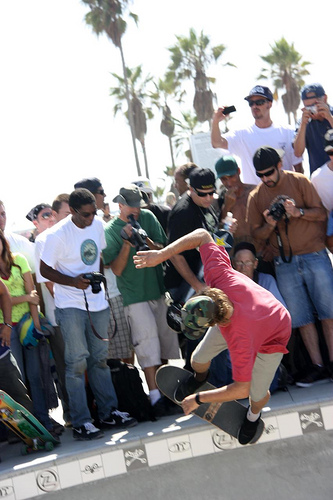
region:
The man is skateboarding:
[156, 234, 319, 417]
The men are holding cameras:
[48, 198, 314, 330]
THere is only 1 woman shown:
[1, 82, 316, 321]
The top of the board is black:
[152, 347, 288, 476]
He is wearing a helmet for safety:
[170, 286, 258, 331]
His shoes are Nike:
[61, 411, 153, 446]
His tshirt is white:
[28, 189, 121, 349]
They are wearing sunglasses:
[189, 172, 310, 203]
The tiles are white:
[28, 433, 260, 482]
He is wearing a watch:
[192, 384, 257, 424]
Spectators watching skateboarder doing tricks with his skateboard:
[0, 77, 331, 496]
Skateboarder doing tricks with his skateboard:
[125, 224, 298, 454]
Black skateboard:
[139, 362, 275, 450]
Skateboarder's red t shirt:
[165, 243, 297, 355]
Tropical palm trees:
[76, 0, 220, 187]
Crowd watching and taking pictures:
[4, 78, 329, 293]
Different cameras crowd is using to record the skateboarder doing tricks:
[58, 189, 307, 301]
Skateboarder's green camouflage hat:
[175, 286, 231, 331]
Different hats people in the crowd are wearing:
[106, 80, 327, 223]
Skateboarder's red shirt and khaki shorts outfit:
[156, 232, 296, 427]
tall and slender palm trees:
[50, 16, 306, 160]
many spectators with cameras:
[26, 79, 302, 286]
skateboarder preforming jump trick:
[124, 229, 294, 456]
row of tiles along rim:
[25, 405, 324, 461]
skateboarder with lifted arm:
[124, 222, 302, 447]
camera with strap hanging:
[52, 263, 125, 349]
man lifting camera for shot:
[204, 75, 294, 192]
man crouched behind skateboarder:
[225, 243, 288, 332]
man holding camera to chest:
[244, 131, 325, 283]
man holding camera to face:
[292, 78, 328, 182]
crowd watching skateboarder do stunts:
[2, 174, 302, 435]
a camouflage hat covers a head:
[182, 293, 236, 339]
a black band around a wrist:
[186, 388, 210, 410]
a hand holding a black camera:
[71, 270, 125, 342]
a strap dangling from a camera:
[82, 292, 127, 343]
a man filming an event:
[114, 192, 181, 359]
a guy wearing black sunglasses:
[179, 171, 227, 232]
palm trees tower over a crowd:
[84, 0, 240, 77]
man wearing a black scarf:
[25, 202, 64, 225]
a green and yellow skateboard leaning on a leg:
[2, 396, 60, 450]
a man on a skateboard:
[142, 229, 293, 452]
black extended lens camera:
[79, 270, 121, 343]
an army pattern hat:
[176, 295, 220, 343]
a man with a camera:
[49, 190, 113, 329]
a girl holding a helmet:
[0, 232, 58, 349]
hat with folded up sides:
[110, 183, 152, 211]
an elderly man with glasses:
[230, 242, 264, 282]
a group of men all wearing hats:
[188, 81, 332, 330]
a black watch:
[192, 390, 205, 409]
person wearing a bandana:
[23, 202, 55, 230]